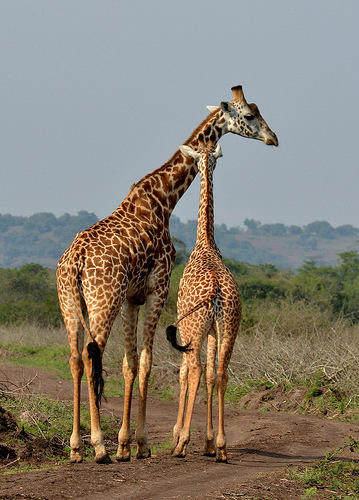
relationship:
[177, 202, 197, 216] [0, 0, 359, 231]
clouds are in blue sky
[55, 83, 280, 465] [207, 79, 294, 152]
adult giraffe has head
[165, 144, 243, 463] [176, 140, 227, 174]
giraffe has head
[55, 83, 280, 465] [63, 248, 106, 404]
adult giraffe has tail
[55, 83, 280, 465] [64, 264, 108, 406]
adult giraffe has tail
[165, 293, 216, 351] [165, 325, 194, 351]
tail has hair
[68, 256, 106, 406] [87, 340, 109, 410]
tail has hair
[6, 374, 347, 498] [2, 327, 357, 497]
dirt on ground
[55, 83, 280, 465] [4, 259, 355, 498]
adult giraffe in wasteland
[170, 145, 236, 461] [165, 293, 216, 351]
giraffe has tail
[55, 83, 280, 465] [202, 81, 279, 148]
adult giraffe has head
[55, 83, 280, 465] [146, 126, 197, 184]
adult giraffe has neck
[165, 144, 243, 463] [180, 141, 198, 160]
giraffe has ear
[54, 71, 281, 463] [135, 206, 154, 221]
adult giraffe has brown spot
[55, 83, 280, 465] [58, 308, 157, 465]
adult giraffe has legs